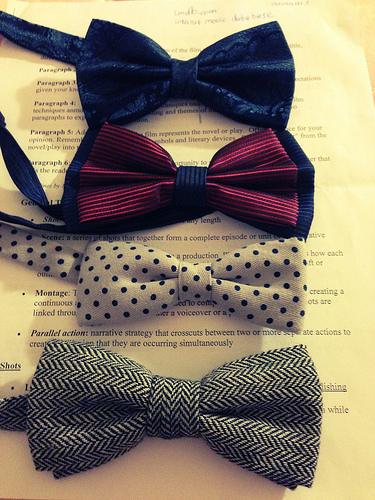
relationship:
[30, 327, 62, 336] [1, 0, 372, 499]
word in book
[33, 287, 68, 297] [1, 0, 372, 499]
word in book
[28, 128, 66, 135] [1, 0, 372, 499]
word in book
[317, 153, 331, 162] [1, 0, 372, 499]
word in book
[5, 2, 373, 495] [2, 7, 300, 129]
paper under bowtie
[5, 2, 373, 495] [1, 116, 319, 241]
paper under bowtie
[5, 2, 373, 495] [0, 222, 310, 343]
paper under bowtie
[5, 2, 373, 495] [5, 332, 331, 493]
paper under bowtie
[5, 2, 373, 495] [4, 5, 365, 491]
paper under bowties